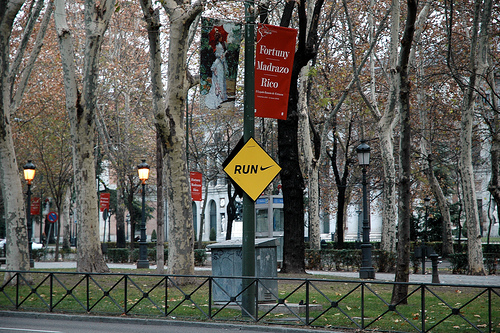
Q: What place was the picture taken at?
A: It was taken at the park.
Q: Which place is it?
A: It is a park.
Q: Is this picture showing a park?
A: Yes, it is showing a park.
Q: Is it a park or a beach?
A: It is a park.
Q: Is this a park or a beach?
A: It is a park.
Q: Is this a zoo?
A: No, it is a park.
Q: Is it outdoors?
A: Yes, it is outdoors.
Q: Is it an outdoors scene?
A: Yes, it is outdoors.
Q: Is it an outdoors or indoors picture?
A: It is outdoors.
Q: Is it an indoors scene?
A: No, it is outdoors.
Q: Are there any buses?
A: No, there are no buses.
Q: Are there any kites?
A: No, there are no kites.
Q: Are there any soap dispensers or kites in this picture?
A: No, there are no kites or soap dispensers.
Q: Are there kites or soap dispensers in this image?
A: No, there are no kites or soap dispensers.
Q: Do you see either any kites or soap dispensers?
A: No, there are no kites or soap dispensers.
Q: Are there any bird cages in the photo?
A: No, there are no bird cages.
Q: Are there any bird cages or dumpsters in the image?
A: No, there are no bird cages or dumpsters.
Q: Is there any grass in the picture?
A: Yes, there is grass.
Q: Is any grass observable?
A: Yes, there is grass.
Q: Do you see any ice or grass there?
A: Yes, there is grass.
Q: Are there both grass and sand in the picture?
A: No, there is grass but no sand.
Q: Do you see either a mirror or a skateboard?
A: No, there are no skateboards or mirrors.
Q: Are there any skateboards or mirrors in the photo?
A: No, there are no skateboards or mirrors.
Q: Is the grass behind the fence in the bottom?
A: Yes, the grass is behind the fence.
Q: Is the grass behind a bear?
A: No, the grass is behind the fence.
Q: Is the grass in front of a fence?
A: No, the grass is behind a fence.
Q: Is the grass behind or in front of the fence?
A: The grass is behind the fence.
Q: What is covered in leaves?
A: The trees are covered in leaves.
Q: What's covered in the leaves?
A: The trees are covered in leaves.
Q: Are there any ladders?
A: No, there are no ladders.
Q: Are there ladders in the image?
A: No, there are no ladders.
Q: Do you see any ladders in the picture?
A: No, there are no ladders.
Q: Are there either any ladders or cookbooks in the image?
A: No, there are no ladders or cookbooks.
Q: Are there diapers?
A: No, there are no diapers.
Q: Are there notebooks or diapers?
A: No, there are no diapers or notebooks.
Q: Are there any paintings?
A: No, there are no paintings.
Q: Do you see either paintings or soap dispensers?
A: No, there are no paintings or soap dispensers.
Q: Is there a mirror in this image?
A: No, there are no mirrors.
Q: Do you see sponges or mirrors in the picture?
A: No, there are no mirrors or sponges.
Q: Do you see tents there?
A: No, there are no tents.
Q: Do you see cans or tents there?
A: No, there are no tents or cans.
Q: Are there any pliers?
A: No, there are no pliers.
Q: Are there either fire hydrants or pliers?
A: No, there are no pliers or fire hydrants.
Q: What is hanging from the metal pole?
A: The flags are hanging from the pole.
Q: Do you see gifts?
A: No, there are no gifts.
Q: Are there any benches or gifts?
A: No, there are no gifts or benches.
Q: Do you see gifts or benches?
A: No, there are no gifts or benches.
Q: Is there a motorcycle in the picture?
A: No, there are no motorcycles.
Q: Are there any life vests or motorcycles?
A: No, there are no motorcycles or life vests.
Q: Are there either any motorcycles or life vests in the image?
A: No, there are no motorcycles or life vests.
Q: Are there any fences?
A: Yes, there is a fence.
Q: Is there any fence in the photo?
A: Yes, there is a fence.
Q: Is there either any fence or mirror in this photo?
A: Yes, there is a fence.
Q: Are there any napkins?
A: No, there are no napkins.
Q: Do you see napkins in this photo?
A: No, there are no napkins.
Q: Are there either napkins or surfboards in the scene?
A: No, there are no napkins or surfboards.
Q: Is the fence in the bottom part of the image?
A: Yes, the fence is in the bottom of the image.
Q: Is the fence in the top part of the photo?
A: No, the fence is in the bottom of the image.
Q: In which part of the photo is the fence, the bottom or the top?
A: The fence is in the bottom of the image.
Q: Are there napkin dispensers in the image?
A: No, there are no napkin dispensers.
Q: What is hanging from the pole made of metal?
A: The flags are hanging from the pole.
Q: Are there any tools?
A: No, there are no tools.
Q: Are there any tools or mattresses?
A: No, there are no tools or mattresses.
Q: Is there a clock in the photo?
A: No, there are no clocks.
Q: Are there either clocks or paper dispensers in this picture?
A: No, there are no clocks or paper dispensers.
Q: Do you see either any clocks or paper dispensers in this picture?
A: No, there are no clocks or paper dispensers.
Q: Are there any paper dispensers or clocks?
A: No, there are no clocks or paper dispensers.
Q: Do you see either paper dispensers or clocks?
A: No, there are no clocks or paper dispensers.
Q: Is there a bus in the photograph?
A: No, there are no buses.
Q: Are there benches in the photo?
A: No, there are no benches.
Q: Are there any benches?
A: No, there are no benches.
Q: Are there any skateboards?
A: No, there are no skateboards.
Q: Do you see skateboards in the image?
A: No, there are no skateboards.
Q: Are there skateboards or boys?
A: No, there are no skateboards or boys.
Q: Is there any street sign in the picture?
A: Yes, there is a street sign.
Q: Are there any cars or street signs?
A: Yes, there is a street sign.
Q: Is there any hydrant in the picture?
A: No, there are no fire hydrants.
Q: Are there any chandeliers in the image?
A: No, there are no chandeliers.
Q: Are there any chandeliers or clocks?
A: No, there are no chandeliers or clocks.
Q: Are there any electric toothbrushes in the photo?
A: No, there are no electric toothbrushes.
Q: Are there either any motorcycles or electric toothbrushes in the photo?
A: No, there are no electric toothbrushes or motorcycles.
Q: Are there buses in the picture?
A: No, there are no buses.